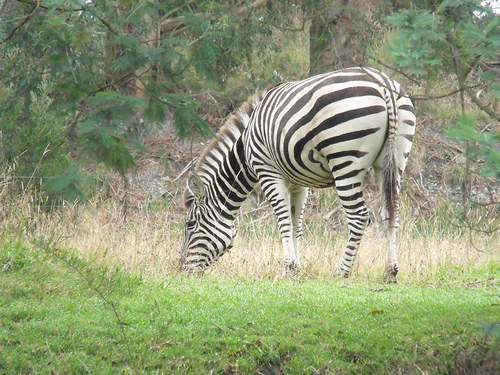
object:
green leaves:
[440, 118, 498, 144]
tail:
[376, 81, 404, 243]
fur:
[380, 144, 406, 233]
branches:
[146, 17, 186, 46]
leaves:
[77, 114, 123, 150]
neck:
[194, 132, 260, 216]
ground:
[0, 190, 500, 374]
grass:
[0, 210, 500, 374]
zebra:
[179, 67, 418, 279]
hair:
[167, 81, 282, 211]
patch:
[390, 262, 497, 347]